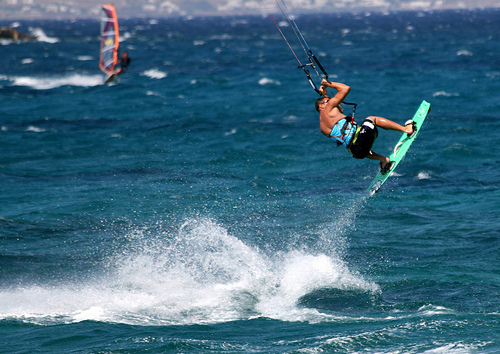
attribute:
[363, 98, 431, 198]
ski board — green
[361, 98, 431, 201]
surfboard — teal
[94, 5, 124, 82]
waterski sail — orange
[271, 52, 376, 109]
handles — black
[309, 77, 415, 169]
person —  surfing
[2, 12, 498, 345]
water — blue-green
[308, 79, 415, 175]
man —  surfing